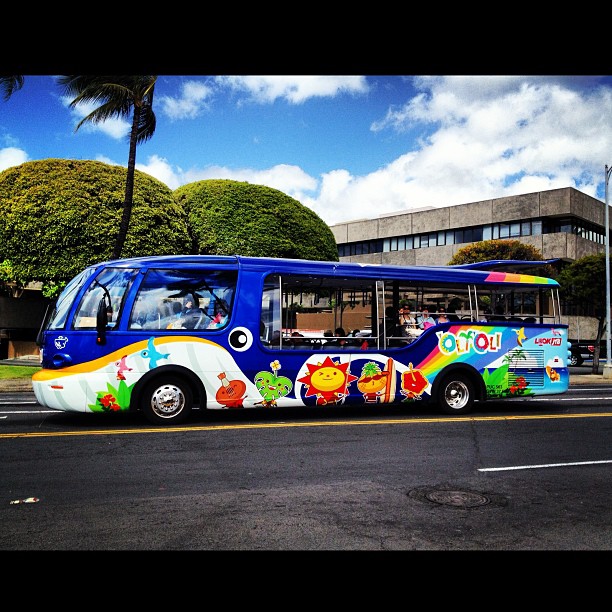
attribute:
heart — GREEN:
[252, 371, 293, 405]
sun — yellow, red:
[295, 357, 356, 400]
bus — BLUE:
[31, 252, 573, 425]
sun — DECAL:
[33, 254, 572, 418]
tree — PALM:
[2, 208, 338, 262]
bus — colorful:
[28, 247, 571, 411]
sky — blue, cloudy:
[0, 76, 609, 192]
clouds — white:
[0, 76, 609, 192]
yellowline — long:
[183, 416, 434, 427]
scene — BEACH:
[444, 320, 565, 394]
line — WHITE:
[469, 451, 593, 483]